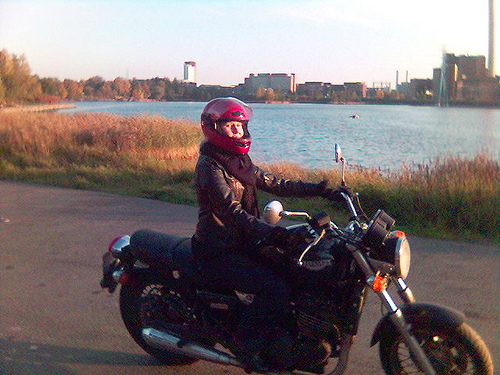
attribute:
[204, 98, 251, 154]
helmet — red, shielded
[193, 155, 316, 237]
jacket — leather, brown, black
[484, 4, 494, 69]
smokestack — in distance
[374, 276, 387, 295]
light — orange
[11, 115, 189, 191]
grass — tall, brown, green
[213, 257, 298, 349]
jeans — blue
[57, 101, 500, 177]
lake — blue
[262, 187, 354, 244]
gloves — black